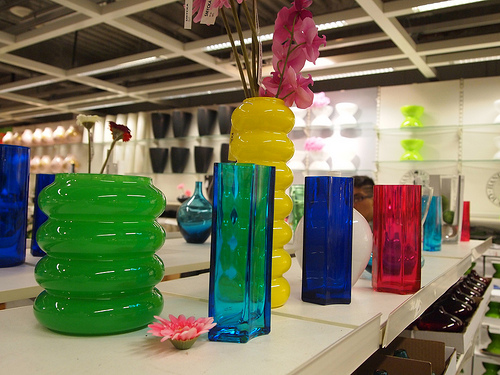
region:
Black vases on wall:
[150, 110, 234, 174]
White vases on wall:
[282, 102, 359, 172]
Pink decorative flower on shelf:
[147, 312, 217, 351]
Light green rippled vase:
[33, 174, 163, 336]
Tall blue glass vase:
[207, 160, 274, 342]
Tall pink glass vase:
[370, 184, 424, 295]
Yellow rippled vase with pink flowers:
[184, 1, 329, 310]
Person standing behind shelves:
[347, 174, 377, 224]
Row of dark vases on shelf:
[410, 267, 495, 349]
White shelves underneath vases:
[2, 218, 499, 373]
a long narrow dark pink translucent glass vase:
[373, 181, 419, 291]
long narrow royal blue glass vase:
[301, 175, 348, 301]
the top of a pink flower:
[146, 310, 213, 345]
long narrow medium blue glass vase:
[209, 161, 275, 341]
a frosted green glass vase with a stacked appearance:
[33, 172, 165, 334]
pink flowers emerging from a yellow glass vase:
[183, 1, 326, 311]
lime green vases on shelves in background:
[377, 78, 460, 171]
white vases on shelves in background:
[286, 100, 368, 173]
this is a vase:
[44, 175, 160, 329]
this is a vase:
[213, 170, 278, 338]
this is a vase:
[226, 105, 289, 156]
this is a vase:
[301, 182, 353, 298]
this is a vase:
[370, 190, 421, 295]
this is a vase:
[440, 174, 463, 212]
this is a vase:
[174, 184, 206, 234]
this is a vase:
[1, 147, 33, 256]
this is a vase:
[44, 165, 169, 322]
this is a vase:
[212, 170, 271, 327]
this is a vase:
[226, 102, 305, 159]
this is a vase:
[301, 179, 362, 289]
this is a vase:
[369, 175, 424, 296]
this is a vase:
[427, 195, 446, 245]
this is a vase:
[457, 202, 472, 231]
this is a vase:
[176, 190, 207, 250]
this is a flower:
[264, 27, 331, 86]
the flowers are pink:
[152, 312, 217, 339]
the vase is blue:
[208, 163, 273, 351]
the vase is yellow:
[233, 93, 298, 316]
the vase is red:
[370, 180, 421, 295]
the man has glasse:
[351, 171, 392, 289]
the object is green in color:
[392, 100, 424, 129]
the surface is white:
[74, 346, 151, 373]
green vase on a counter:
[33, 167, 168, 335]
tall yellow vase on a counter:
[230, 90, 293, 309]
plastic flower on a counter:
[145, 310, 216, 354]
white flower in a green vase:
[74, 110, 100, 175]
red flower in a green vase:
[103, 118, 132, 175]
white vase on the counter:
[292, 200, 376, 290]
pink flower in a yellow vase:
[258, 4, 320, 110]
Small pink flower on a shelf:
[142, 305, 217, 348]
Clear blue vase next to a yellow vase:
[200, 157, 275, 342]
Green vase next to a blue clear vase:
[30, 170, 165, 335]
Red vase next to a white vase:
[370, 181, 421, 291]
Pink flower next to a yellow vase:
[275, 61, 312, 106]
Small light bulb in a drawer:
[420, 310, 460, 330]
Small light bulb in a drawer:
[437, 290, 472, 315]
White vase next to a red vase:
[292, 200, 369, 285]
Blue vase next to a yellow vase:
[300, 175, 351, 303]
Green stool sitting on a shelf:
[397, 101, 426, 127]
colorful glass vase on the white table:
[31, 172, 167, 328]